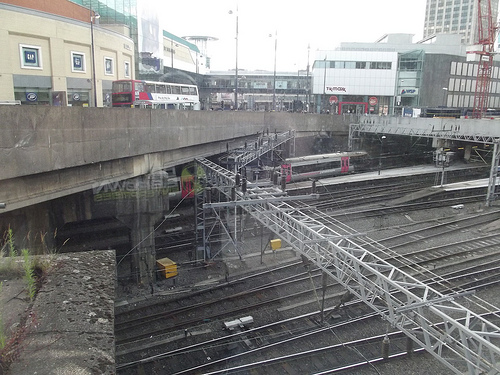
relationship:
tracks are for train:
[82, 203, 499, 374] [150, 148, 340, 197]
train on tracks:
[150, 148, 340, 197] [82, 203, 499, 374]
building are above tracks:
[421, 5, 499, 111] [82, 203, 499, 374]